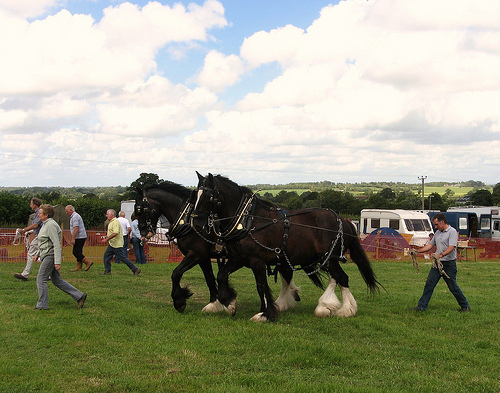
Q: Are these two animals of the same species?
A: Yes, all the animals are horses.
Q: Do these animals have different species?
A: No, all the animals are horses.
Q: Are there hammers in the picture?
A: No, there are no hammers.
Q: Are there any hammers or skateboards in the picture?
A: No, there are no hammers or skateboards.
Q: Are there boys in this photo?
A: No, there are no boys.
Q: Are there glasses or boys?
A: No, there are no boys or glasses.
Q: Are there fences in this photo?
A: Yes, there is a fence.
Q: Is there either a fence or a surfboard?
A: Yes, there is a fence.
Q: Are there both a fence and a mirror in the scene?
A: No, there is a fence but no mirrors.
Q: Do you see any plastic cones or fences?
A: Yes, there is a plastic fence.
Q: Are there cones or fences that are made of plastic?
A: Yes, the fence is made of plastic.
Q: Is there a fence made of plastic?
A: Yes, there is a fence that is made of plastic.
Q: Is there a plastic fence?
A: Yes, there is a fence that is made of plastic.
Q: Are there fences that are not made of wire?
A: Yes, there is a fence that is made of plastic.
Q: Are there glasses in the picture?
A: No, there are no glasses.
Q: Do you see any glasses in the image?
A: No, there are no glasses.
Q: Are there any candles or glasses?
A: No, there are no glasses or candles.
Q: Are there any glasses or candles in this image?
A: No, there are no glasses or candles.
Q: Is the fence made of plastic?
A: Yes, the fence is made of plastic.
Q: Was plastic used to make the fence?
A: Yes, the fence is made of plastic.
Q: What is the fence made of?
A: The fence is made of plastic.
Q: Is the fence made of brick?
A: No, the fence is made of plastic.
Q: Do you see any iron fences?
A: No, there is a fence but it is made of plastic.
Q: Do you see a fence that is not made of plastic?
A: No, there is a fence but it is made of plastic.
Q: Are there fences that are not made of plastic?
A: No, there is a fence but it is made of plastic.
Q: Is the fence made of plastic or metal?
A: The fence is made of plastic.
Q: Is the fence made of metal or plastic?
A: The fence is made of plastic.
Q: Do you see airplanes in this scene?
A: No, there are no airplanes.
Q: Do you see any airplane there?
A: No, there are no airplanes.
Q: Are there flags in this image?
A: No, there are no flags.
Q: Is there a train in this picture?
A: No, there are no trains.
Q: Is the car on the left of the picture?
A: No, the car is on the right of the image.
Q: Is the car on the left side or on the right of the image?
A: The car is on the right of the image.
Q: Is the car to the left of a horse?
A: No, the car is to the right of a horse.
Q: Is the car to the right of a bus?
A: No, the car is to the right of the horse.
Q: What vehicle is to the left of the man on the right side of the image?
A: The vehicle is a car.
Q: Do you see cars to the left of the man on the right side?
A: Yes, there is a car to the left of the man.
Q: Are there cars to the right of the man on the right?
A: No, the car is to the left of the man.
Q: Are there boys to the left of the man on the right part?
A: No, there is a car to the left of the man.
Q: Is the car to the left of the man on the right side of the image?
A: Yes, the car is to the left of the man.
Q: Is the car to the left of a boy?
A: No, the car is to the left of the man.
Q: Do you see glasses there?
A: No, there are no glasses.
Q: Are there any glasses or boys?
A: No, there are no glasses or boys.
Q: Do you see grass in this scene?
A: Yes, there is grass.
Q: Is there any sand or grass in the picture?
A: Yes, there is grass.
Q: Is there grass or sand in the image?
A: Yes, there is grass.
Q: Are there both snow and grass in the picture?
A: No, there is grass but no snow.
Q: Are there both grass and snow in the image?
A: No, there is grass but no snow.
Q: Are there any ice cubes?
A: No, there are no ice cubes.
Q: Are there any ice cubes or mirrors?
A: No, there are no ice cubes or mirrors.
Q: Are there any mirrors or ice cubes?
A: No, there are no ice cubes or mirrors.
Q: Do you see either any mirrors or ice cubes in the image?
A: No, there are no ice cubes or mirrors.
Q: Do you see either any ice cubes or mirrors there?
A: No, there are no ice cubes or mirrors.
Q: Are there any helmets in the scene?
A: No, there are no helmets.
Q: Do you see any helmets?
A: No, there are no helmets.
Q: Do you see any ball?
A: No, there are no balls.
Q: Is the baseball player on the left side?
A: Yes, the player is on the left of the image.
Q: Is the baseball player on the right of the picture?
A: No, the player is on the left of the image.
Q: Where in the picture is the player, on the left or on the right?
A: The player is on the left of the image.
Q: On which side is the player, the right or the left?
A: The player is on the left of the image.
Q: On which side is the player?
A: The player is on the left of the image.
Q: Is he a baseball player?
A: Yes, that is a baseball player.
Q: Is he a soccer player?
A: No, that is a baseball player.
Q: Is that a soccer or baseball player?
A: That is a baseball player.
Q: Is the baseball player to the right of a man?
A: Yes, the player is to the right of a man.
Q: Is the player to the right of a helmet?
A: No, the player is to the right of a man.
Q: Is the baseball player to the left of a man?
A: No, the player is to the right of a man.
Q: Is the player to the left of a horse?
A: Yes, the player is to the left of a horse.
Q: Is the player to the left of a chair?
A: No, the player is to the left of a horse.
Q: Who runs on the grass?
A: The player runs on the grass.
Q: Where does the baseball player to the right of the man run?
A: The player runs on the grass.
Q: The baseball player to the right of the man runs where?
A: The player runs on the grass.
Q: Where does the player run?
A: The player runs on the grass.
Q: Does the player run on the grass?
A: Yes, the player runs on the grass.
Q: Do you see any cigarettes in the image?
A: No, there are no cigarettes.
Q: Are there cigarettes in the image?
A: No, there are no cigarettes.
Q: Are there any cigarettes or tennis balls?
A: No, there are no cigarettes or tennis balls.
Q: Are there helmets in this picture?
A: No, there are no helmets.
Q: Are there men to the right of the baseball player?
A: Yes, there is a man to the right of the player.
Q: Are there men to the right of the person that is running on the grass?
A: Yes, there is a man to the right of the player.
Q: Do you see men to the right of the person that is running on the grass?
A: Yes, there is a man to the right of the player.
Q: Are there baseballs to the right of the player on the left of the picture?
A: No, there is a man to the right of the player.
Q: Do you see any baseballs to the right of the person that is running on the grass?
A: No, there is a man to the right of the player.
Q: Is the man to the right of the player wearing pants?
A: Yes, the man is wearing pants.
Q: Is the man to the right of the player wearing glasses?
A: No, the man is wearing pants.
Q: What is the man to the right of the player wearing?
A: The man is wearing trousers.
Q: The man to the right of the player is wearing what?
A: The man is wearing trousers.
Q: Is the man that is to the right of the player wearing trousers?
A: Yes, the man is wearing trousers.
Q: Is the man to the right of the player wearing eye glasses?
A: No, the man is wearing trousers.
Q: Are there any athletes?
A: No, there are no athletes.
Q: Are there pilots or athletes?
A: No, there are no athletes or pilots.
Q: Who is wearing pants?
A: The man is wearing pants.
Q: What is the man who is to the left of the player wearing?
A: The man is wearing pants.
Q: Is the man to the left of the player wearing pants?
A: Yes, the man is wearing pants.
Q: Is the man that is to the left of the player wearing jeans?
A: No, the man is wearing pants.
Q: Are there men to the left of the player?
A: Yes, there is a man to the left of the player.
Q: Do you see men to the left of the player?
A: Yes, there is a man to the left of the player.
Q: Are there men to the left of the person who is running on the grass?
A: Yes, there is a man to the left of the player.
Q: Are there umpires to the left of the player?
A: No, there is a man to the left of the player.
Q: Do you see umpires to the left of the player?
A: No, there is a man to the left of the player.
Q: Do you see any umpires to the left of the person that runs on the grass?
A: No, there is a man to the left of the player.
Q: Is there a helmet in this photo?
A: No, there are no helmets.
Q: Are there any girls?
A: No, there are no girls.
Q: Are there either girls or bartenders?
A: No, there are no girls or bartenders.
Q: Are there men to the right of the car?
A: Yes, there is a man to the right of the car.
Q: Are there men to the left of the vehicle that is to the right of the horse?
A: No, the man is to the right of the car.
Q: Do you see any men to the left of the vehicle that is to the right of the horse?
A: No, the man is to the right of the car.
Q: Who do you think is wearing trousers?
A: The man is wearing trousers.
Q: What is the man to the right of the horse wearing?
A: The man is wearing trousers.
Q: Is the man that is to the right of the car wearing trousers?
A: Yes, the man is wearing trousers.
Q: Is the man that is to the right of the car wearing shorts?
A: No, the man is wearing trousers.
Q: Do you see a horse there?
A: Yes, there is a horse.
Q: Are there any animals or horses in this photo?
A: Yes, there is a horse.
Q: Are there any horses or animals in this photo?
A: Yes, there is a horse.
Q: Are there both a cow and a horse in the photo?
A: No, there is a horse but no cows.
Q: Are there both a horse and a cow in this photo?
A: No, there is a horse but no cows.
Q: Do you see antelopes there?
A: No, there are no antelopes.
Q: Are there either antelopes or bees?
A: No, there are no antelopes or bees.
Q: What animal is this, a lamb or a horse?
A: This is a horse.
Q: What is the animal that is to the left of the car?
A: The animal is a horse.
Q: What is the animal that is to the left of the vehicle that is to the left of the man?
A: The animal is a horse.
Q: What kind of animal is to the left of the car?
A: The animal is a horse.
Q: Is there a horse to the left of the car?
A: Yes, there is a horse to the left of the car.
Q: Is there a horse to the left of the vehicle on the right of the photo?
A: Yes, there is a horse to the left of the car.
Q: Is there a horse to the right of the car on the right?
A: No, the horse is to the left of the car.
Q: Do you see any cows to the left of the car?
A: No, there is a horse to the left of the car.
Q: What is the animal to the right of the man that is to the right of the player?
A: The animal is a horse.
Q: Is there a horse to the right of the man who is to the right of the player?
A: Yes, there is a horse to the right of the man.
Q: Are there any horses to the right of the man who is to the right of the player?
A: Yes, there is a horse to the right of the man.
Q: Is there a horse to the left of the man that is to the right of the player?
A: No, the horse is to the right of the man.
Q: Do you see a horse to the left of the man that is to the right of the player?
A: No, the horse is to the right of the man.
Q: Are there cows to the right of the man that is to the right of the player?
A: No, there is a horse to the right of the man.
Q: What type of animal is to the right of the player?
A: The animal is a horse.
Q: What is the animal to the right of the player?
A: The animal is a horse.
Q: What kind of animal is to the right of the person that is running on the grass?
A: The animal is a horse.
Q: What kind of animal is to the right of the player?
A: The animal is a horse.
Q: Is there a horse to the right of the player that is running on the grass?
A: Yes, there is a horse to the right of the player.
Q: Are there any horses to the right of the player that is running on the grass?
A: Yes, there is a horse to the right of the player.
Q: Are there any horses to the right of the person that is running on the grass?
A: Yes, there is a horse to the right of the player.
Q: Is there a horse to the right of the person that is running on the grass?
A: Yes, there is a horse to the right of the player.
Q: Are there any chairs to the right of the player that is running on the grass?
A: No, there is a horse to the right of the player.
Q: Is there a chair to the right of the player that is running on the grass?
A: No, there is a horse to the right of the player.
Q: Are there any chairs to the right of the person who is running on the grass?
A: No, there is a horse to the right of the player.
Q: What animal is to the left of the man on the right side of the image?
A: The animal is a horse.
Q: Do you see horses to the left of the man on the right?
A: Yes, there is a horse to the left of the man.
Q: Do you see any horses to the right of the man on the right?
A: No, the horse is to the left of the man.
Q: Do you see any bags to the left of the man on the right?
A: No, there is a horse to the left of the man.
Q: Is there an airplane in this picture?
A: No, there are no airplanes.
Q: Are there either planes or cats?
A: No, there are no planes or cats.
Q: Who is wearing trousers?
A: The man is wearing trousers.